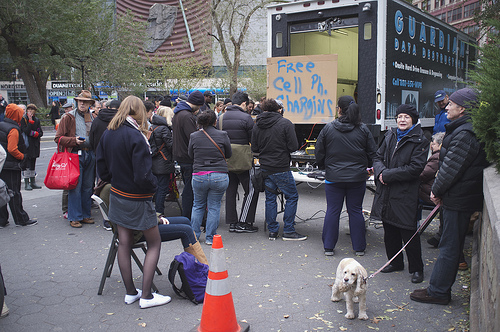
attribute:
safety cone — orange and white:
[188, 229, 244, 330]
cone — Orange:
[187, 231, 254, 328]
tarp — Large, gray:
[142, 2, 178, 52]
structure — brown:
[115, 0, 211, 74]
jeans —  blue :
[186, 165, 227, 231]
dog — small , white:
[296, 239, 408, 322]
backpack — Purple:
[171, 256, 213, 304]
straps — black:
[167, 259, 177, 298]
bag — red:
[39, 143, 84, 193]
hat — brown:
[70, 77, 103, 103]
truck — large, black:
[265, 2, 495, 182]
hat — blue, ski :
[448, 81, 481, 108]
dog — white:
[330, 257, 368, 319]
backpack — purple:
[169, 250, 209, 303]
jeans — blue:
[184, 162, 227, 215]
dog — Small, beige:
[322, 192, 442, 323]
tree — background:
[6, 4, 117, 121]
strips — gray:
[200, 230, 230, 302]